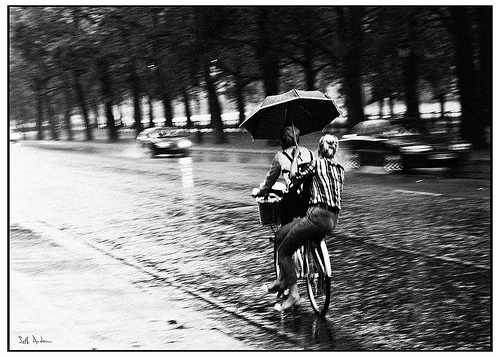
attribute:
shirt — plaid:
[290, 153, 347, 215]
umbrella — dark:
[236, 93, 349, 136]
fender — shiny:
[314, 236, 334, 281]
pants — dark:
[274, 199, 342, 282]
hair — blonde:
[315, 130, 339, 159]